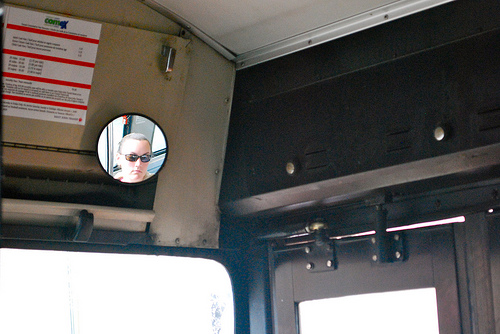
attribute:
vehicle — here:
[36, 40, 441, 321]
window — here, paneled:
[26, 252, 158, 324]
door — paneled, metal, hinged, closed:
[270, 215, 487, 334]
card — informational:
[13, 34, 97, 136]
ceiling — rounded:
[147, 9, 285, 64]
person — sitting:
[112, 131, 156, 185]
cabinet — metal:
[267, 158, 316, 186]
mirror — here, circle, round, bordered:
[75, 95, 195, 194]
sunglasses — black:
[121, 146, 160, 164]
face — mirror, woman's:
[118, 126, 157, 162]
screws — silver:
[423, 116, 469, 146]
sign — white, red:
[35, 32, 71, 107]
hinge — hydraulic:
[252, 217, 379, 259]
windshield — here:
[56, 230, 267, 333]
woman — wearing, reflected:
[113, 132, 170, 192]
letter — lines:
[12, 36, 50, 104]